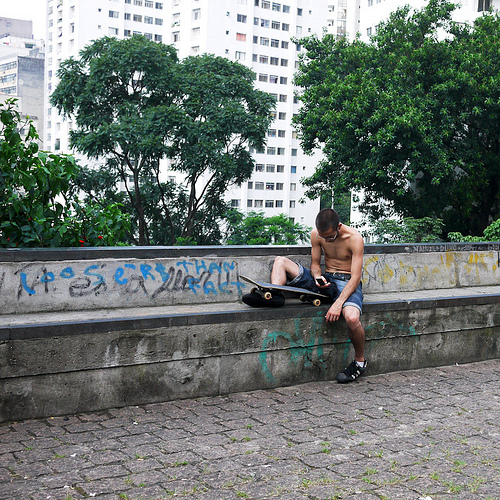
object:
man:
[240, 205, 376, 383]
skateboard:
[238, 272, 327, 308]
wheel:
[262, 289, 273, 301]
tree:
[47, 30, 278, 245]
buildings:
[42, 0, 164, 245]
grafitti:
[18, 258, 248, 298]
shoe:
[240, 287, 287, 308]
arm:
[323, 237, 365, 322]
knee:
[343, 313, 361, 330]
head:
[313, 207, 342, 243]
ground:
[3, 357, 499, 499]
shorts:
[288, 260, 366, 315]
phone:
[314, 276, 326, 288]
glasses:
[316, 232, 339, 242]